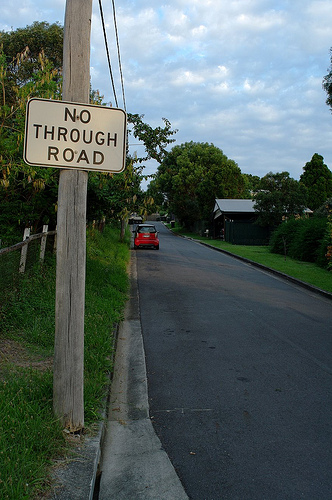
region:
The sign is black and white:
[23, 97, 124, 171]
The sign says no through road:
[32, 101, 118, 165]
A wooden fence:
[1, 224, 53, 266]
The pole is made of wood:
[54, 0, 92, 432]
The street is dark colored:
[142, 275, 307, 426]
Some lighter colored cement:
[107, 425, 161, 489]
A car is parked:
[132, 223, 159, 248]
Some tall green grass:
[6, 385, 51, 492]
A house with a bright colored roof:
[211, 197, 311, 245]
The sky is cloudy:
[161, 28, 284, 124]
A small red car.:
[134, 224, 160, 249]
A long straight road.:
[132, 211, 330, 497]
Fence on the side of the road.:
[0, 210, 117, 279]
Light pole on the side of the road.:
[57, 0, 86, 443]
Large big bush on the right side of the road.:
[149, 141, 250, 241]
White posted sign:
[27, 98, 122, 174]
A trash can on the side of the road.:
[169, 219, 176, 229]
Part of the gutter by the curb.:
[89, 463, 104, 499]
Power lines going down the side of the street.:
[95, 0, 125, 155]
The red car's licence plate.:
[141, 233, 150, 237]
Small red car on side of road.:
[131, 223, 154, 243]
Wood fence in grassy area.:
[6, 221, 62, 278]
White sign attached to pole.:
[23, 103, 136, 174]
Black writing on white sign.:
[23, 105, 141, 163]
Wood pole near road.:
[35, 150, 109, 410]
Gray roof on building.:
[216, 197, 303, 223]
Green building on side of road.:
[214, 215, 287, 248]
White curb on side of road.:
[118, 247, 143, 499]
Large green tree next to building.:
[162, 139, 253, 236]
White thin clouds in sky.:
[243, 140, 298, 168]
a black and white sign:
[24, 95, 132, 173]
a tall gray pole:
[55, 168, 92, 433]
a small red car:
[134, 224, 162, 251]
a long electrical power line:
[93, 2, 130, 110]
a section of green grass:
[203, 231, 329, 297]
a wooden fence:
[16, 221, 52, 266]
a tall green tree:
[155, 137, 245, 235]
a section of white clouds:
[128, 6, 187, 64]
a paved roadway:
[127, 212, 329, 498]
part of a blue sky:
[257, 0, 283, 11]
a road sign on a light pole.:
[12, 94, 135, 177]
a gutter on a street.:
[100, 235, 196, 498]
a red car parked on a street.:
[131, 218, 163, 260]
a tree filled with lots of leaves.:
[146, 137, 251, 240]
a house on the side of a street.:
[205, 190, 325, 243]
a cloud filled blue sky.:
[0, 0, 331, 192]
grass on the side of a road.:
[0, 224, 133, 498]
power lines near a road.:
[94, 0, 146, 198]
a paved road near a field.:
[127, 216, 330, 495]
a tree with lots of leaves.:
[311, 58, 330, 117]